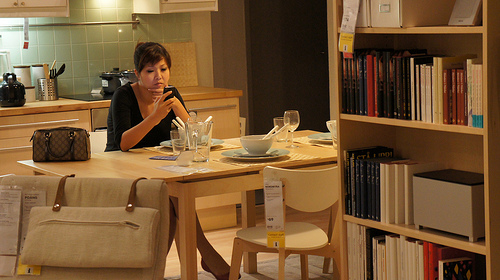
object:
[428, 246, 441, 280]
book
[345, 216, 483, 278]
shelf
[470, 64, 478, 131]
book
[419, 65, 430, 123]
white book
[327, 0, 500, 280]
bookshelf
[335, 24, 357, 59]
tag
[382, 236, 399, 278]
book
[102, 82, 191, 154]
shirt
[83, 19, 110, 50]
tile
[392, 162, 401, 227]
white book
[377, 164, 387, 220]
white book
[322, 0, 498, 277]
tan shelf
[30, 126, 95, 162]
bag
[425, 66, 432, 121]
book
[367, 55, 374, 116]
red books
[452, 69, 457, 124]
red books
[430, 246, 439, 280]
red books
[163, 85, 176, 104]
cell phone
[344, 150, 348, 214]
book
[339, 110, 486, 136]
shelf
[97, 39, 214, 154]
woman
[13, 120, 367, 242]
table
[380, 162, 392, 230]
book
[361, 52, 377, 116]
book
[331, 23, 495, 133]
shelf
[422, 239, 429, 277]
book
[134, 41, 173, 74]
hair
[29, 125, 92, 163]
gray purse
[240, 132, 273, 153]
white bowl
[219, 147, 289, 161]
plate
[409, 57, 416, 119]
book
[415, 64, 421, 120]
book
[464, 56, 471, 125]
book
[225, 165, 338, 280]
chair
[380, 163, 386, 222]
book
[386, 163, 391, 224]
book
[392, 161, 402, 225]
book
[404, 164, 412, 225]
book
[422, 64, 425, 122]
book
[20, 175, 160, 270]
bag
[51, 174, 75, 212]
handles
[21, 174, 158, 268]
organizer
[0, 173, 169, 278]
chair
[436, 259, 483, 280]
book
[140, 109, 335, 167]
tableware set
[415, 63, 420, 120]
book